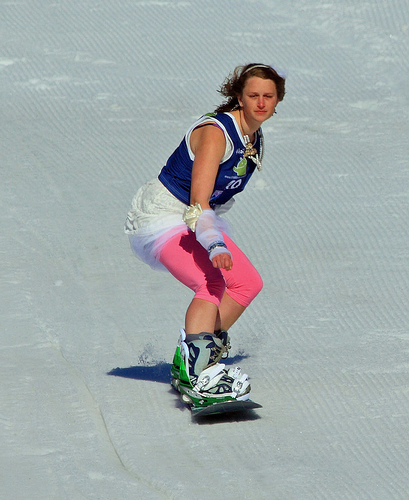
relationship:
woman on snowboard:
[125, 62, 283, 400] [165, 367, 264, 427]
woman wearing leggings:
[125, 62, 283, 400] [143, 214, 265, 311]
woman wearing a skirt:
[125, 62, 283, 400] [126, 177, 238, 252]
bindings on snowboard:
[176, 349, 229, 407] [165, 367, 264, 427]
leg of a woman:
[154, 229, 225, 337] [125, 62, 283, 400]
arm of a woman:
[189, 132, 244, 277] [125, 62, 283, 400]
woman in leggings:
[125, 62, 283, 400] [143, 214, 265, 311]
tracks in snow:
[34, 117, 135, 285] [6, 5, 405, 496]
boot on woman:
[188, 330, 253, 401] [125, 62, 283, 400]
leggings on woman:
[143, 214, 265, 311] [125, 62, 283, 400]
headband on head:
[240, 64, 276, 76] [228, 57, 290, 127]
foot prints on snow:
[32, 67, 142, 116] [6, 5, 405, 496]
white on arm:
[188, 207, 226, 256] [189, 132, 244, 277]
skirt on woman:
[126, 177, 238, 252] [125, 62, 283, 400]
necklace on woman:
[234, 108, 261, 161] [125, 62, 283, 400]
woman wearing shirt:
[125, 62, 283, 400] [163, 108, 266, 207]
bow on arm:
[182, 203, 200, 232] [189, 132, 244, 277]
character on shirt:
[232, 156, 252, 180] [163, 108, 266, 207]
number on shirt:
[224, 180, 245, 192] [163, 108, 266, 207]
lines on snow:
[101, 19, 382, 116] [6, 5, 405, 496]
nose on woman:
[256, 97, 272, 111] [125, 62, 283, 400]